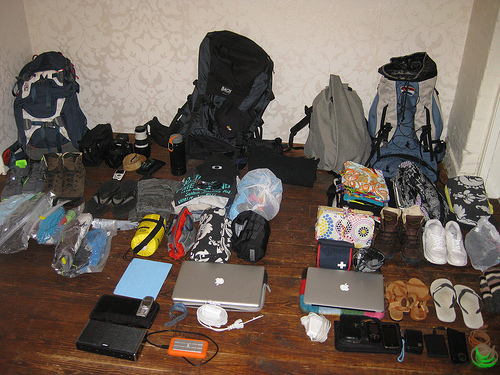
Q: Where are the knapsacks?
A: Against wall.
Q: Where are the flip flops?
A: Right front.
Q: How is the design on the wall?
A: Wall paper.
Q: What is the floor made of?
A: Wood.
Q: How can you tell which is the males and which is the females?
A: Style.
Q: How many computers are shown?
A: Two.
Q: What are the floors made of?
A: Wood.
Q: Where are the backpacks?
A: Against wall.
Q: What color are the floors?
A: Brown.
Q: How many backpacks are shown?
A: Four.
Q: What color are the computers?
A: Silver.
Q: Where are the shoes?
A: On floor.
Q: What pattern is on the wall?
A: Baroque.